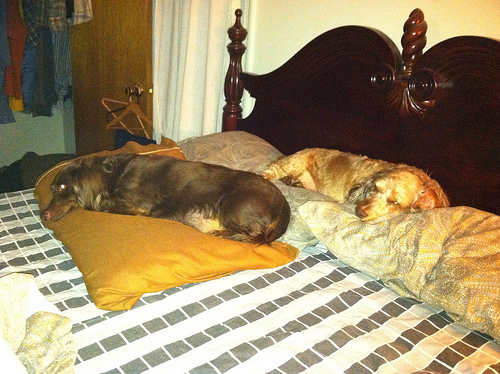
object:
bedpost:
[220, 6, 243, 132]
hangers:
[101, 96, 153, 139]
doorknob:
[125, 87, 143, 97]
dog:
[41, 150, 288, 246]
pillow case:
[177, 131, 344, 242]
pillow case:
[351, 210, 497, 268]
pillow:
[175, 131, 353, 250]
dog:
[259, 147, 450, 222]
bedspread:
[0, 185, 498, 373]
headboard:
[219, 7, 500, 218]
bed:
[0, 131, 499, 374]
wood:
[314, 88, 393, 141]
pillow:
[32, 135, 298, 311]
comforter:
[3, 180, 498, 370]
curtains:
[154, 0, 246, 143]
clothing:
[3, 0, 94, 124]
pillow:
[297, 202, 499, 342]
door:
[66, 0, 151, 158]